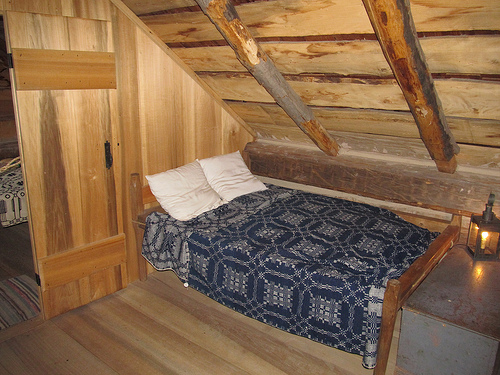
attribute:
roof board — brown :
[186, 2, 349, 176]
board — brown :
[255, 37, 395, 77]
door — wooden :
[1, 8, 142, 328]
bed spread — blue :
[139, 181, 441, 368]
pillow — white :
[130, 147, 295, 228]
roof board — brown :
[280, 48, 384, 126]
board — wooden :
[126, 156, 461, 373]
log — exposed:
[194, 0, 341, 155]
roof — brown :
[107, 0, 498, 200]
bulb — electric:
[473, 225, 498, 253]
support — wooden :
[364, 1, 465, 177]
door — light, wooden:
[4, 12, 151, 323]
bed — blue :
[144, 153, 462, 370]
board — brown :
[117, 0, 498, 177]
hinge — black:
[31, 271, 49, 290]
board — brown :
[166, 37, 498, 76]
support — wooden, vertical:
[360, 0, 458, 173]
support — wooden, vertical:
[194, 1, 341, 155]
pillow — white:
[143, 159, 230, 224]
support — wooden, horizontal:
[36, 230, 126, 290]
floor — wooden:
[1, 220, 401, 373]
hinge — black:
[5, 51, 15, 69]